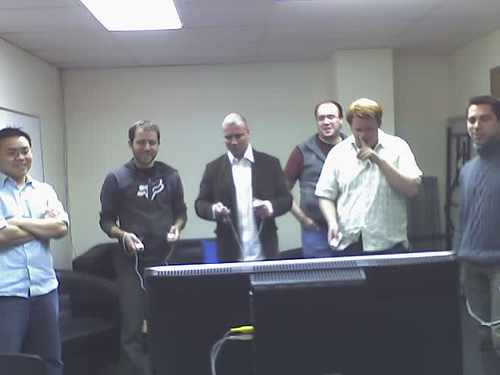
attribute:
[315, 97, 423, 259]
man — playing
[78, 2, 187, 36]
light — white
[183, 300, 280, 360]
cord — yellow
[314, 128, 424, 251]
shirt — button up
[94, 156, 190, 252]
shirt — black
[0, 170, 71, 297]
shirt — blue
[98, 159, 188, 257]
hoodie — black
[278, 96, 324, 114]
light — white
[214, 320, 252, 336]
cord — yellow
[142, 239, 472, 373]
tv screen — black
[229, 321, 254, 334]
cord — yellow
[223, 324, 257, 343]
cord — yellow